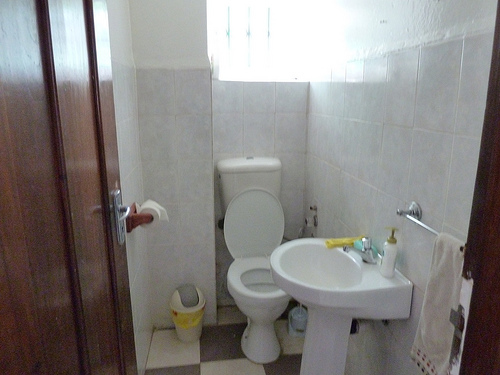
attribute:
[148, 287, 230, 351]
bin — white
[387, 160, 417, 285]
bottle — white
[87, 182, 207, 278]
tissue — white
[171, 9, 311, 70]
window — bright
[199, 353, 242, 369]
tile — white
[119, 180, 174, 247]
paper — white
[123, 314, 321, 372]
tiles — black, white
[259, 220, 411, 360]
sink — white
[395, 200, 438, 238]
towel bar — metal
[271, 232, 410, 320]
sink — white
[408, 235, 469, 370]
towel — white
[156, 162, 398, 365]
toilet — white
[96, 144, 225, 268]
paper — white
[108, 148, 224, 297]
paper — white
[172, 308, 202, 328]
bag — YELLOW 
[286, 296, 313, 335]
brush — WHITE 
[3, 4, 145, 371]
door — wooden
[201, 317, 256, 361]
tile — white , black 